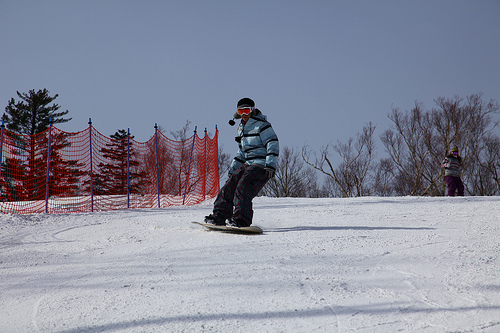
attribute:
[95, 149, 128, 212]
fence — orange, plastic, red, mesh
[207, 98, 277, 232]
snowboarder — snowboarding, going, woman, girl, lady, person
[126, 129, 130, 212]
post — blue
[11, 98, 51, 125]
tree — pine, evergreen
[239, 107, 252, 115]
goggles — red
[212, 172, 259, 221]
pants — black, baggy, dark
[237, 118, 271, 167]
jacket — blue, silver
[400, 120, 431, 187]
tree — bare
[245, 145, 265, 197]
clothing — winter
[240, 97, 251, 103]
helmet — black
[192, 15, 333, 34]
sky — blue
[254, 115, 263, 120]
hood — silver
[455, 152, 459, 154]
goggles — black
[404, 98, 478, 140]
trees — bare